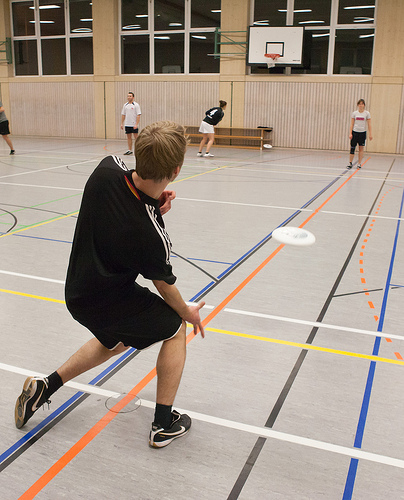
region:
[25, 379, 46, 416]
White Nike logo on black shoe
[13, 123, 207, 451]
Man throwing white frisbee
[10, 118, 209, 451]
Man wearing black shirt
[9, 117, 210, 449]
Man wearing black shorts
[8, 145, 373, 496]
Orange straight line on court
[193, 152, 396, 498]
Black straight line on court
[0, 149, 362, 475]
Blue straight line on court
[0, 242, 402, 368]
Yellow straight line on court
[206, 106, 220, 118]
4 printed in white on black shirt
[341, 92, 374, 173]
Woman wearing gray top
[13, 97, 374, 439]
two people playing frisbee together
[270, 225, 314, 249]
a white frisbee thrown in the air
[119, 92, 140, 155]
a man standing in a gymnasium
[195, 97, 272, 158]
a woman throwing a frisbee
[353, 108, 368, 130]
woman wearing a gray shirt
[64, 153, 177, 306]
man wearing a black shirt with white lines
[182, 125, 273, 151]
a wooden bench in a gymnasium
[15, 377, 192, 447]
man wearing black and white sneakers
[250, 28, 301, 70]
a basketball hoop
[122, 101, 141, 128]
man wearing a white shirt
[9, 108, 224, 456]
guy with light brown hair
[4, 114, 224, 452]
guy wearing black shirt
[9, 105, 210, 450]
guy wearing black shorts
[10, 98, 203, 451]
guy wearing black and white tennis shoes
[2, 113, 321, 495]
guy playing frisbee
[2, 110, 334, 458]
guy about to catch frisbee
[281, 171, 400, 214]
lines on the ground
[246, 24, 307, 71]
basketball court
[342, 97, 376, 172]
girl wearing red and white shirt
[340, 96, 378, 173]
girl wearing black shorts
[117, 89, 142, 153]
Man wearing gray shirt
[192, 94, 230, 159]
Woman wearing black shirt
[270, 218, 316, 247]
Round white frisbee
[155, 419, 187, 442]
White Nike logo on black shoe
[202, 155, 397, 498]
Straight black line on court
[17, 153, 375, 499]
Straight orange line on court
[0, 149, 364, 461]
Straight blue line on court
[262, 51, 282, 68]
orange and white baskeball hoop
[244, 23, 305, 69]
backboard and basketball hoop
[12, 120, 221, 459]
man on a court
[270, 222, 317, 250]
white frisbee in mid air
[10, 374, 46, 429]
white and black shoe on the man's foot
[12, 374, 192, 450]
black and white shoes on a man's feet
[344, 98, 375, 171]
woman standing on a court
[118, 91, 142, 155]
man standing on a court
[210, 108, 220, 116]
white design on the back of the woman's sweater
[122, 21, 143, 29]
light reflected on a window